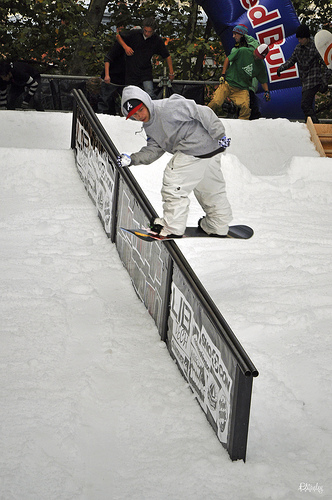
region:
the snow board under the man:
[118, 223, 254, 240]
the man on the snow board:
[115, 84, 237, 236]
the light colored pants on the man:
[153, 149, 232, 236]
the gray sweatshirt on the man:
[120, 84, 228, 165]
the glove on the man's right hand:
[115, 153, 130, 166]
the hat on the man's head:
[120, 97, 143, 121]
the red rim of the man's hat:
[121, 105, 144, 120]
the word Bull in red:
[257, 23, 300, 82]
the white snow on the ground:
[5, 109, 331, 496]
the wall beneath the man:
[68, 94, 256, 468]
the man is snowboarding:
[98, 76, 258, 260]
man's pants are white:
[173, 135, 257, 232]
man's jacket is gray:
[93, 62, 231, 168]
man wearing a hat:
[116, 91, 146, 120]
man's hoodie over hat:
[112, 80, 155, 127]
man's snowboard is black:
[114, 204, 263, 257]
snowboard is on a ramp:
[126, 215, 271, 254]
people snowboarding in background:
[79, 5, 315, 138]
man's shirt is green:
[219, 39, 271, 95]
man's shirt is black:
[110, 24, 181, 102]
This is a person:
[110, 79, 255, 248]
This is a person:
[112, 10, 174, 105]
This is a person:
[202, 41, 290, 142]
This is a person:
[221, 16, 254, 64]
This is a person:
[275, 25, 331, 130]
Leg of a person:
[195, 162, 254, 279]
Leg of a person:
[152, 146, 203, 256]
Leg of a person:
[235, 86, 257, 128]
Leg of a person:
[205, 69, 237, 127]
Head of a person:
[104, 85, 158, 133]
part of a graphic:
[290, 476, 323, 492]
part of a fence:
[204, 396, 220, 436]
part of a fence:
[220, 412, 256, 458]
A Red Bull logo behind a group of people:
[239, 5, 299, 81]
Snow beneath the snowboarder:
[38, 310, 139, 466]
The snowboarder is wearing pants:
[160, 154, 234, 232]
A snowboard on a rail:
[121, 223, 252, 241]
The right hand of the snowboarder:
[113, 152, 131, 166]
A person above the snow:
[113, 88, 231, 233]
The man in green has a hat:
[254, 42, 270, 54]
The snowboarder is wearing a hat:
[118, 103, 149, 115]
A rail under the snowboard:
[160, 243, 262, 376]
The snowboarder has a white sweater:
[98, 87, 227, 148]